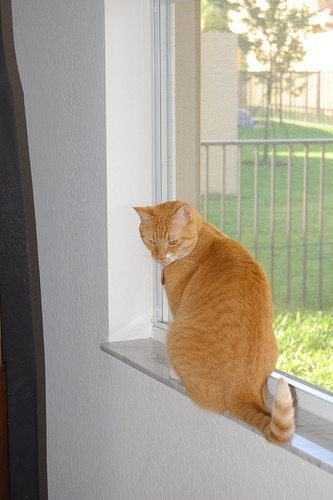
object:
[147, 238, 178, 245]
eyes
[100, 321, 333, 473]
sill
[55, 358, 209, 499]
walls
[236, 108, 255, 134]
ground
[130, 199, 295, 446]
cat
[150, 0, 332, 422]
window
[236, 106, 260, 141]
grill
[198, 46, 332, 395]
yard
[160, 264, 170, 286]
collar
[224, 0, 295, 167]
tree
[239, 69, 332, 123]
fence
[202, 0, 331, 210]
background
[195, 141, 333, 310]
fence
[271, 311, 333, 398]
green grass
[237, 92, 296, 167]
stakes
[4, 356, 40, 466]
bedpost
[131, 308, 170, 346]
seal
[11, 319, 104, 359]
bad sentence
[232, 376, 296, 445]
tail